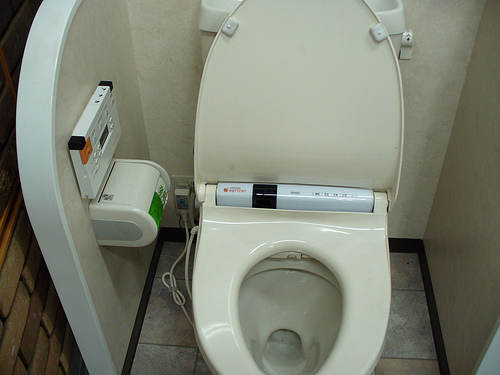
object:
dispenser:
[88, 154, 172, 249]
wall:
[113, 28, 189, 74]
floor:
[149, 330, 184, 358]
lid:
[195, 1, 404, 187]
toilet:
[0, 0, 500, 374]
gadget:
[186, 229, 196, 242]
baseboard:
[413, 242, 432, 271]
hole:
[261, 323, 303, 360]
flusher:
[398, 26, 415, 61]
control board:
[59, 80, 123, 201]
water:
[242, 292, 245, 293]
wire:
[162, 276, 185, 315]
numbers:
[225, 185, 234, 195]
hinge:
[371, 191, 392, 216]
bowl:
[261, 308, 333, 352]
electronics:
[215, 182, 373, 210]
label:
[75, 141, 94, 162]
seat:
[188, 204, 392, 374]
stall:
[33, 31, 124, 57]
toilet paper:
[115, 222, 156, 250]